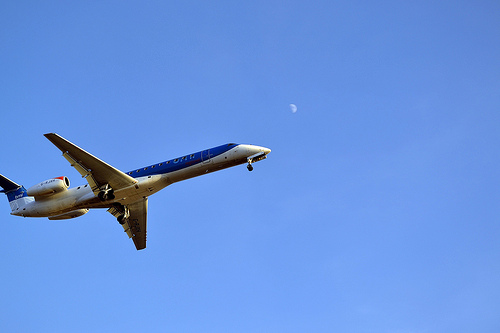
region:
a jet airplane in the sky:
[2, 124, 274, 254]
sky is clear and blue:
[4, 3, 497, 330]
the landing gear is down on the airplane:
[94, 149, 258, 239]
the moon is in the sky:
[277, 96, 304, 124]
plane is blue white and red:
[5, 123, 275, 258]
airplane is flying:
[4, 117, 276, 257]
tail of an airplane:
[1, 171, 28, 207]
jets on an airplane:
[24, 174, 92, 224]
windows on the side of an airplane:
[122, 138, 238, 178]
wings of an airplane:
[42, 128, 155, 254]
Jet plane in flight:
[6, 108, 333, 253]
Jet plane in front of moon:
[198, 70, 335, 205]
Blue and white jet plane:
[0, 111, 280, 273]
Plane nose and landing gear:
[220, 123, 278, 190]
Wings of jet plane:
[30, 117, 173, 273]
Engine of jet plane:
[15, 170, 96, 245]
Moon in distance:
[261, 72, 331, 138]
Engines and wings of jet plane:
[22, 120, 167, 270]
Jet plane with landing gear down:
[40, 97, 280, 264]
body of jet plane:
[88, 138, 281, 190]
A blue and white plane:
[2, 119, 288, 258]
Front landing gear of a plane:
[238, 148, 269, 176]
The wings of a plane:
[41, 120, 151, 257]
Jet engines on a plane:
[18, 168, 88, 223]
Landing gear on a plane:
[95, 150, 261, 220]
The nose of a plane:
[230, 138, 274, 166]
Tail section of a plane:
[0, 169, 37, 222]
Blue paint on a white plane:
[112, 140, 248, 183]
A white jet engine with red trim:
[18, 170, 72, 200]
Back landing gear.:
[82, 173, 144, 233]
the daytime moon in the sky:
[278, 87, 317, 126]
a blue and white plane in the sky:
[9, 126, 292, 253]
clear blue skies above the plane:
[0, 21, 245, 126]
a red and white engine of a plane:
[24, 169, 79, 200]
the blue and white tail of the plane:
[1, 161, 53, 243]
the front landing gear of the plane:
[218, 134, 282, 198]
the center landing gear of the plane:
[85, 175, 141, 238]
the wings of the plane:
[47, 119, 169, 285]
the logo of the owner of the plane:
[11, 187, 29, 204]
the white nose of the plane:
[240, 138, 287, 180]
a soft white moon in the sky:
[282, 82, 321, 130]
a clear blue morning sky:
[321, 150, 460, 239]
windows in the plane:
[151, 158, 203, 161]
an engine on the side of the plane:
[26, 168, 83, 198]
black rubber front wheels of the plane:
[244, 156, 256, 176]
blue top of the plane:
[151, 140, 239, 169]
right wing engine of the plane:
[43, 207, 95, 219]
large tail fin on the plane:
[2, 174, 31, 205]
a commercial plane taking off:
[3, 115, 308, 296]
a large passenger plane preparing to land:
[0, 101, 304, 288]